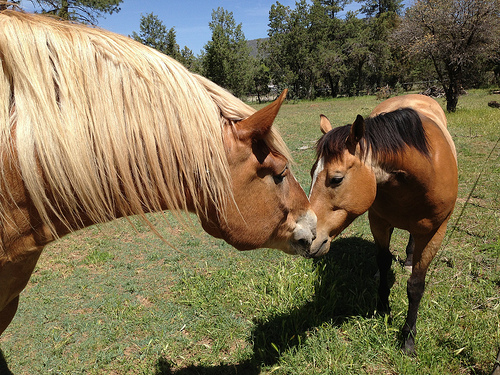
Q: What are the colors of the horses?
A: Brown.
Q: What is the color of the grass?
A: Green.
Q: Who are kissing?
A: Horses.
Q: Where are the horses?
A: On the field.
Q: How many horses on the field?
A: Two.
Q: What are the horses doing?
A: Kissing.